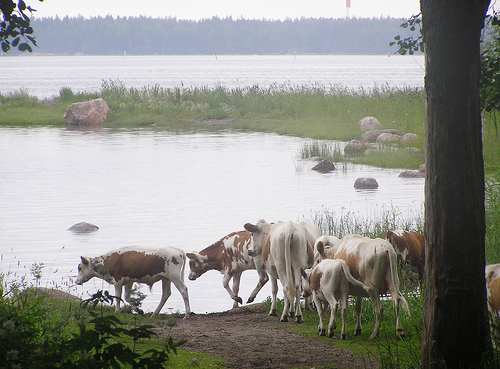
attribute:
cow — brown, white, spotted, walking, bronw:
[64, 239, 195, 306]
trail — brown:
[205, 320, 245, 343]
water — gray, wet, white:
[109, 203, 125, 224]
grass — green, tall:
[290, 102, 333, 124]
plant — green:
[100, 312, 157, 357]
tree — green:
[397, 22, 421, 58]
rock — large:
[56, 99, 119, 126]